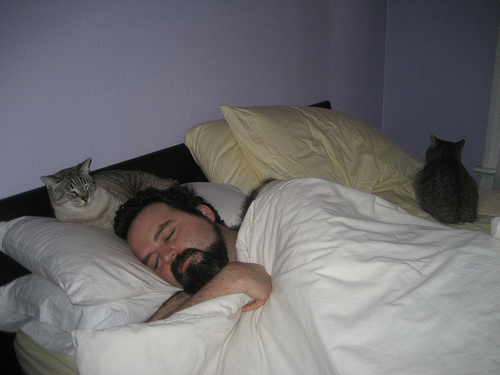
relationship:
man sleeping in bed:
[112, 174, 500, 371] [3, 98, 496, 370]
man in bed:
[112, 174, 500, 371] [3, 98, 496, 370]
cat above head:
[43, 161, 179, 232] [112, 174, 227, 300]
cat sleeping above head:
[43, 161, 179, 232] [112, 174, 227, 300]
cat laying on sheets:
[413, 132, 482, 227] [183, 97, 498, 220]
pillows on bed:
[181, 95, 439, 215] [3, 98, 496, 370]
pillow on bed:
[0, 181, 245, 306] [3, 98, 496, 370]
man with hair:
[112, 174, 500, 371] [111, 185, 228, 241]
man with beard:
[112, 174, 500, 371] [169, 223, 228, 298]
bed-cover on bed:
[55, 175, 499, 367] [3, 98, 496, 370]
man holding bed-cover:
[112, 174, 500, 371] [55, 175, 499, 367]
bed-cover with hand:
[55, 175, 499, 367] [213, 254, 276, 310]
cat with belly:
[43, 161, 179, 232] [84, 202, 112, 221]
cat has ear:
[43, 161, 179, 232] [78, 155, 99, 171]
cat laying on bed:
[413, 132, 482, 227] [3, 98, 496, 370]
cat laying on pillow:
[43, 161, 179, 232] [9, 181, 245, 310]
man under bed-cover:
[112, 174, 500, 371] [70, 176, 500, 375]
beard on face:
[169, 223, 228, 298] [128, 196, 234, 293]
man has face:
[112, 174, 500, 371] [128, 196, 234, 293]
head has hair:
[112, 174, 227, 300] [111, 185, 228, 241]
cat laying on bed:
[43, 161, 179, 232] [3, 98, 496, 370]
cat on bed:
[43, 161, 179, 232] [3, 98, 496, 370]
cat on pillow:
[43, 161, 179, 232] [9, 181, 245, 310]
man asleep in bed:
[112, 174, 500, 371] [3, 98, 496, 370]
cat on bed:
[413, 132, 482, 227] [3, 98, 496, 370]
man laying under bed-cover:
[112, 174, 500, 371] [70, 176, 500, 375]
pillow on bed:
[9, 181, 245, 310] [3, 98, 496, 370]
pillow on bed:
[1, 280, 163, 352] [3, 98, 496, 370]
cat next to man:
[43, 161, 179, 232] [112, 174, 500, 371]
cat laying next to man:
[43, 161, 179, 232] [112, 174, 500, 371]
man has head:
[112, 174, 500, 371] [112, 174, 227, 300]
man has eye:
[112, 174, 500, 371] [163, 229, 179, 246]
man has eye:
[112, 174, 500, 371] [151, 253, 161, 274]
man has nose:
[112, 174, 500, 371] [156, 244, 179, 265]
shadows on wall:
[256, 11, 392, 105] [5, 0, 500, 200]